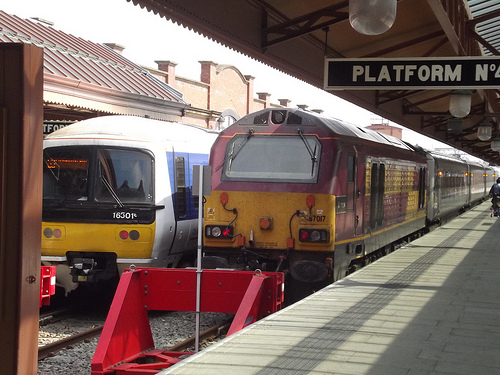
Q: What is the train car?
A: Red and yellow.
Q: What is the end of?
A: Train car.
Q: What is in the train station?
A: Part of the concrete walkway.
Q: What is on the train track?
A: Red triangular shaped blockade.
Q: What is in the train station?
A: Part of the roof.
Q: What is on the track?
A: Two trains.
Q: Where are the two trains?
A: Next to one another.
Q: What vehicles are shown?
A: Trains.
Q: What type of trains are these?
A: Passenger.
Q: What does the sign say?
A: Platform.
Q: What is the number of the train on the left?
A: 16501.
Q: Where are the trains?
A: Station.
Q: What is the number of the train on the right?
A: 47017.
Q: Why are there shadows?
A: Sunny.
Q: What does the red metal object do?
A: Stops train.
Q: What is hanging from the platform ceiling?
A: Lights.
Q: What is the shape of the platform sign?
A: Rectangle.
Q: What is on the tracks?
A: Two passenger trains.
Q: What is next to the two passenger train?
A: Platform.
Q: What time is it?
A: Afternoon.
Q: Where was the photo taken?
A: At a train station.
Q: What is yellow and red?
A: The train.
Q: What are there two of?
A: Trains.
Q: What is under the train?
A: Tracks.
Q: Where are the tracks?
A: Under the train.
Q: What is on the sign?
A: The word "platform".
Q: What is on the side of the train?
A: Windows.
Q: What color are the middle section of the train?
A: Yellow.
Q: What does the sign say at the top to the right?
A: Platform.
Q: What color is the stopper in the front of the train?
A: Red.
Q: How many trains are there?
A: Two.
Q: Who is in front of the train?
A: No one.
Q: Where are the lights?
A: In front of the train.